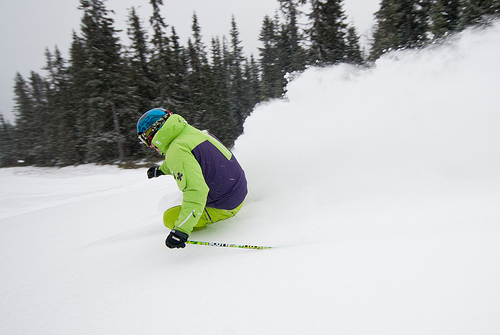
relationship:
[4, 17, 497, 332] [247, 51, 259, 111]
snow is on tree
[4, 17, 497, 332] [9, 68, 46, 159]
snow covered tree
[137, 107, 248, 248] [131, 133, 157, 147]
man wearing goggles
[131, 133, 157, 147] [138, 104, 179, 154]
goggles on head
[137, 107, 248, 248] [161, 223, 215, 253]
man wearing gloves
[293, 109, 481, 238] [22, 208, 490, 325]
snow on ground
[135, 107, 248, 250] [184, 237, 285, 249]
man holding skiing sticks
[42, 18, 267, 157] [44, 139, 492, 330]
trees are next to field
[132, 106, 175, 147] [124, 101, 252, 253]
helmet on person